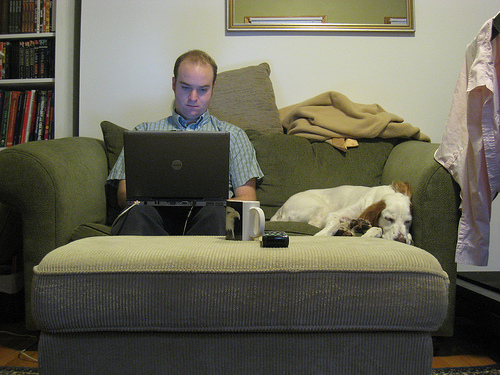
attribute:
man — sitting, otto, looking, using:
[81, 33, 297, 242]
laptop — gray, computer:
[105, 121, 268, 216]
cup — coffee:
[210, 182, 279, 257]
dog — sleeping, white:
[262, 166, 442, 252]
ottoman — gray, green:
[218, 203, 242, 239]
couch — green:
[37, 109, 452, 285]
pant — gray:
[121, 202, 232, 237]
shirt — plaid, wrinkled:
[236, 124, 267, 173]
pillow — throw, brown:
[231, 59, 286, 131]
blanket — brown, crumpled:
[286, 75, 404, 164]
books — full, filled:
[7, 33, 60, 79]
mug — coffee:
[222, 188, 270, 248]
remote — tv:
[260, 222, 297, 254]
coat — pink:
[417, 55, 489, 166]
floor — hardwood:
[8, 334, 42, 364]